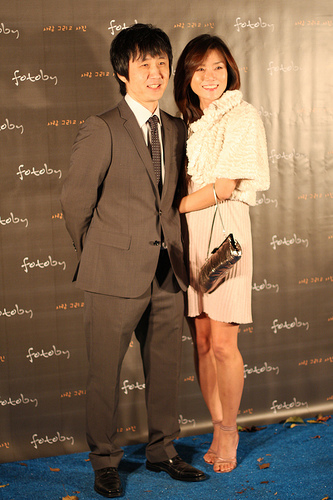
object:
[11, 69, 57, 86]
word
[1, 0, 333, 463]
wall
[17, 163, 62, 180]
word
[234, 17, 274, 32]
word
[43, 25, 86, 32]
word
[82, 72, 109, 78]
word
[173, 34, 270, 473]
woman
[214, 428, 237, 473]
foot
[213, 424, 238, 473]
shoe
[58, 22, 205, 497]
man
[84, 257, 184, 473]
pants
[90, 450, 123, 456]
wrinkle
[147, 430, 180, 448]
wrinkle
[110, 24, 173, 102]
head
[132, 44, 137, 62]
bangs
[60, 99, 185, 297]
jacket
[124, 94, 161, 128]
collar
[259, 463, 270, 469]
leaf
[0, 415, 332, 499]
floor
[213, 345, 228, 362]
knee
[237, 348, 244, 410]
muscle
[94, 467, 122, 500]
shoe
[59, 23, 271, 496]
couple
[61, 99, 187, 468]
suit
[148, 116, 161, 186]
tie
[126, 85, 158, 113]
neck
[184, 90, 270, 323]
dress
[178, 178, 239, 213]
arm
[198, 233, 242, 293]
purse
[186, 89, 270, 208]
cape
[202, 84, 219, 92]
smile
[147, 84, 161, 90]
smile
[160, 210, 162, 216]
button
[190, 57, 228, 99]
face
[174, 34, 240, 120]
hair